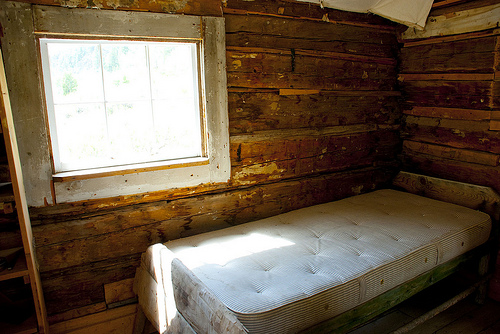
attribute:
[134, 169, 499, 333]
bed — green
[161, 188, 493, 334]
mattress — stacked, white, dirty, bare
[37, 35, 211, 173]
window — divided, dirty, bare, square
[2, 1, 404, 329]
wall — brown, tan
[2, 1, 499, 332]
cabin — rustic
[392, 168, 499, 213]
headboard — wooden, small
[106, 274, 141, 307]
board — white, standing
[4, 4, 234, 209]
paint — white, peeling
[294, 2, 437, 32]
insulation — falling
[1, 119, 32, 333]
shelf — wooden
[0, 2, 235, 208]
trim — white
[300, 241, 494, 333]
box spring — green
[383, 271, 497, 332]
pole — metal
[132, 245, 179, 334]
cloth — dirty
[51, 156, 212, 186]
ledge — flat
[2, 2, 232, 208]
wood — white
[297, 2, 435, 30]
ceiling — falling, hanging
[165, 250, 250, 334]
footboard — white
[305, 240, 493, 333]
board — green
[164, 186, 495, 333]
cot — single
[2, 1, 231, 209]
frame — white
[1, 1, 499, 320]
logs — missing, old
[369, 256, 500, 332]
frame — metal